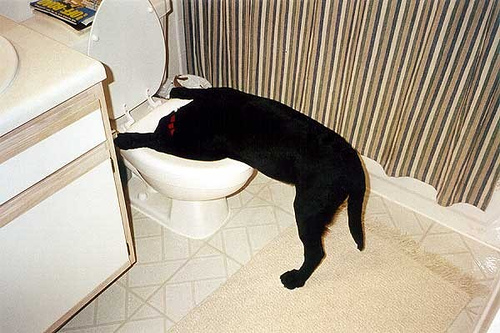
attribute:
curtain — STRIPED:
[166, 8, 494, 212]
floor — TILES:
[78, 186, 498, 323]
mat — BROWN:
[157, 206, 489, 327]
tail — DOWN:
[342, 166, 372, 256]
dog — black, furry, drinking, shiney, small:
[106, 79, 371, 294]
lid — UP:
[80, 0, 172, 127]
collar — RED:
[166, 111, 174, 134]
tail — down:
[345, 170, 375, 254]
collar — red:
[161, 109, 181, 141]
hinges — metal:
[109, 156, 131, 266]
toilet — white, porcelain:
[90, 3, 247, 244]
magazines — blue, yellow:
[30, 0, 98, 29]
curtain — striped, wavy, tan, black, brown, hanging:
[194, 4, 499, 81]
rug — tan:
[195, 289, 471, 330]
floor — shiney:
[476, 235, 500, 277]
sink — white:
[1, 16, 58, 120]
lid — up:
[103, 0, 172, 116]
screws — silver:
[145, 90, 153, 101]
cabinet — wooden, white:
[1, 150, 142, 310]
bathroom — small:
[24, 4, 491, 327]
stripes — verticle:
[392, 44, 435, 154]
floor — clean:
[118, 275, 213, 303]